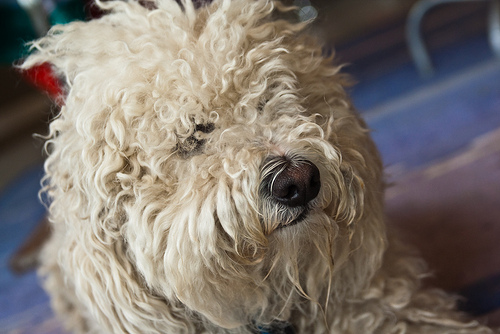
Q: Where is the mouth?
A: On dog.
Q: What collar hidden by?
A: Hair.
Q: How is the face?
A: Fuzzy.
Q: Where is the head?
A: On dog.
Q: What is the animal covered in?
A: Fur.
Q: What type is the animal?
A: A dog.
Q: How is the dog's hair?
A: Long, curly and white.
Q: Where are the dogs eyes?
A: Behind the dog's fur.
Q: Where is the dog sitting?
A: On the floor.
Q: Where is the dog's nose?
A: Above the mouth.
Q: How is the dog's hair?
A: Curly.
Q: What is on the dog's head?
A: Curly fur.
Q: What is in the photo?
A: A dog.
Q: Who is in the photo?
A: A dog.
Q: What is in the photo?
A: A white dog.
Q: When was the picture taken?
A: During the day.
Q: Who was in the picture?
A: There are no people in the picture.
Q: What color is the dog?
A: White.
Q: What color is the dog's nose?
A: Black.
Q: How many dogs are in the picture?
A: One.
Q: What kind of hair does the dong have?
A: Long wavy hair.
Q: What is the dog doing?
A: Looking at the camera.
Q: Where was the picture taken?
A: Near a shaggy dog.